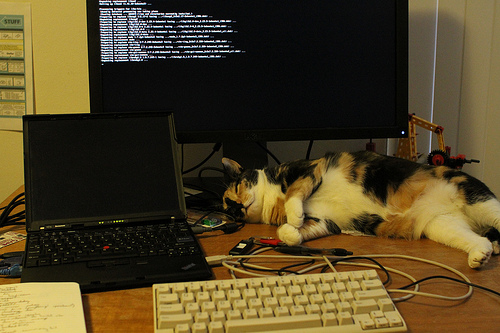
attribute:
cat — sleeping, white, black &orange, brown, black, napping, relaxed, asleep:
[217, 154, 498, 269]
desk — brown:
[2, 183, 495, 331]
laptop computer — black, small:
[22, 113, 212, 291]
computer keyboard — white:
[154, 271, 404, 332]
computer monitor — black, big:
[86, 0, 410, 208]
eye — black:
[227, 204, 237, 216]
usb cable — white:
[206, 253, 470, 301]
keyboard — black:
[27, 220, 194, 265]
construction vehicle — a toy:
[395, 114, 480, 175]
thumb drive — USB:
[230, 236, 254, 256]